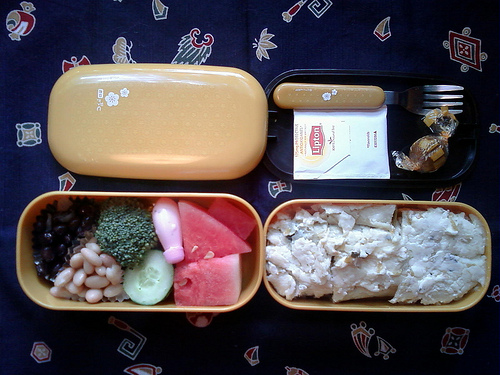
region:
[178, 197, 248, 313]
The pieces of watermelon.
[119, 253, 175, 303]
The piece of cucumber.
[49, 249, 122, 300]
The beige beans next to the cucumber.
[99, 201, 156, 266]
The piece of broccoli next to the beans.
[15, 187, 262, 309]
The container on the left.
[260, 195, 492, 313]
The container on the right.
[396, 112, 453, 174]
The piece of wrapped candy.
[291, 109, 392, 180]
The white envelope of Lipton tea.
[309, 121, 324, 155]
The red Lipton label on the envelope.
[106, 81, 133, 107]
The white flowers on the left cover.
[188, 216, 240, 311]
watermelon cut in slices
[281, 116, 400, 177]
a lipton teabag in picture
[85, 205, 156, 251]
this is a broccoli florette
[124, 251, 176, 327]
this is a piece of cucumber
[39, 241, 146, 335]
the meal has beans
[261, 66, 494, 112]
this is a small fork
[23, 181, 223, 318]
a small container of food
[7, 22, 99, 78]
the place mat has a design on it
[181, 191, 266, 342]
three pieces of watermelon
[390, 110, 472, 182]
a piece of candy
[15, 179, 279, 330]
a bowl full of vegetables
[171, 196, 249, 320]
watermelon with seeds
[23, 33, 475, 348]
healthy lunch meal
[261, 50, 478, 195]
lipton tea a fork and a candy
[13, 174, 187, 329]
beans broccoli and cucumber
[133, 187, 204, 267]
something small pink and long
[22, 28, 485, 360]
lunch in two dishes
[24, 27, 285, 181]
flower lunch case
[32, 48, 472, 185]
small fork with matching food container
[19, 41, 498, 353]
healthy portioned and choice lunch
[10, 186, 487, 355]
Two plastic containers filled with food.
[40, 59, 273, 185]
Top of plastic container.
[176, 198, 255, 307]
Watermelon slices in plastic container.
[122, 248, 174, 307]
Sliced cucumber in plastic container.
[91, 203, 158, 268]
Broccoli spear in plastic container.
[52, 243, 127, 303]
Great northern beans in plastic container.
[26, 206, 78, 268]
Black beans in plastic container.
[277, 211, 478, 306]
Strange food substance in plastic container.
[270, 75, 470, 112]
Fork laying inside top of plastic container.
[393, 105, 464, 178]
Piece of candy on top of plastic container.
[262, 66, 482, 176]
blue rectangle plastic tray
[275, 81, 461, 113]
metal fork with plastic handle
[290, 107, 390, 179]
tea bag in wrapper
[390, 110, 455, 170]
wrapped piece of candy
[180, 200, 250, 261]
diced watermelon in tray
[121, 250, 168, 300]
sliced green cucumber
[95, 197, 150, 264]
green broccoli head in tray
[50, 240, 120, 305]
light pink beans in tray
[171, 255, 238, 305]
red diced watermelon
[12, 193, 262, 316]
yellow tray with food